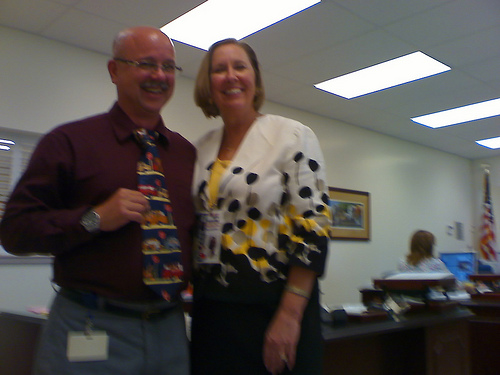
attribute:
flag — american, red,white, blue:
[477, 172, 497, 264]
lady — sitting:
[397, 229, 464, 294]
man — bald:
[1, 26, 199, 373]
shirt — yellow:
[209, 158, 232, 209]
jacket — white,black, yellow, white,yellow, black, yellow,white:
[191, 113, 331, 305]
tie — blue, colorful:
[133, 127, 186, 303]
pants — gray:
[35, 283, 191, 373]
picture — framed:
[326, 198, 365, 231]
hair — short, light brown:
[194, 37, 265, 120]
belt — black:
[56, 282, 183, 321]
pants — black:
[190, 277, 324, 372]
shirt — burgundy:
[1, 100, 197, 300]